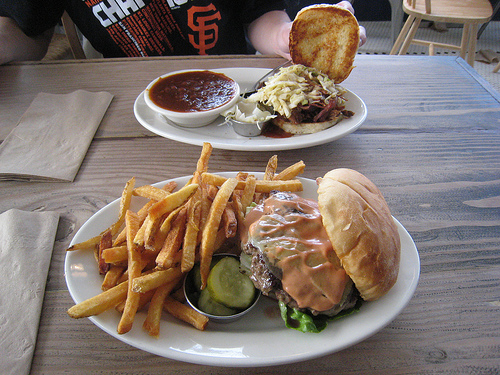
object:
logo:
[185, 3, 224, 58]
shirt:
[21, 0, 283, 58]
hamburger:
[241, 169, 402, 332]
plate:
[63, 171, 421, 366]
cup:
[181, 252, 263, 323]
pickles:
[210, 256, 254, 323]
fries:
[70, 171, 195, 331]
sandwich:
[257, 4, 360, 136]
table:
[367, 42, 496, 374]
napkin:
[0, 202, 63, 374]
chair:
[390, 3, 496, 54]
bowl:
[142, 67, 241, 129]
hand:
[271, 1, 368, 64]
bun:
[288, 4, 359, 84]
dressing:
[288, 258, 337, 289]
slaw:
[252, 63, 339, 116]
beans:
[169, 79, 193, 94]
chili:
[167, 79, 217, 106]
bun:
[317, 166, 402, 302]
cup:
[230, 115, 268, 140]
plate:
[132, 63, 369, 154]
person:
[0, 1, 374, 82]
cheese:
[250, 211, 284, 249]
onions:
[262, 255, 284, 281]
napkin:
[2, 89, 114, 183]